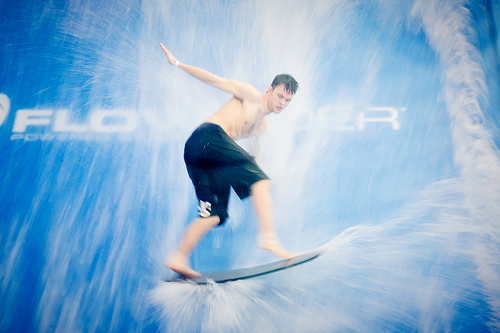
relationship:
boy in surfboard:
[159, 42, 301, 277] [154, 239, 325, 284]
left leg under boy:
[162, 165, 231, 282] [159, 42, 301, 277]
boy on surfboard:
[167, 74, 303, 278] [152, 246, 319, 296]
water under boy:
[2, 2, 497, 330] [159, 42, 301, 277]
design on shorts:
[198, 200, 211, 218] [178, 124, 283, 210]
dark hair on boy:
[273, 70, 300, 90] [227, 58, 307, 143]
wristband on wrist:
[175, 62, 180, 66] [173, 60, 179, 68]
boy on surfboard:
[159, 42, 301, 277] [154, 245, 334, 285]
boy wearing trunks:
[159, 42, 301, 277] [164, 115, 292, 243]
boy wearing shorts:
[159, 42, 301, 277] [180, 121, 267, 229]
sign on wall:
[8, 107, 405, 144] [3, 2, 495, 329]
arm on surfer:
[157, 41, 252, 100] [151, 37, 324, 295]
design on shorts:
[199, 200, 214, 219] [180, 121, 267, 229]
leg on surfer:
[247, 180, 300, 267] [151, 37, 324, 295]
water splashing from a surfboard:
[0, 0, 500, 333] [194, 261, 298, 282]